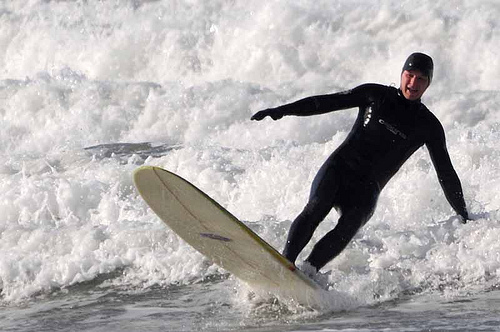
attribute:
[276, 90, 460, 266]
wet suit — tight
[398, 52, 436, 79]
cap — black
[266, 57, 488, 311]
suit — black, wet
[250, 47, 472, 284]
man — surfing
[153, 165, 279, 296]
line —  red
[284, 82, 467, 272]
wetsuit — black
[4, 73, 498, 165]
wave — white, crashing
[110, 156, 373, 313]
surfboard — large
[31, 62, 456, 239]
foam — white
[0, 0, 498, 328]
water — calm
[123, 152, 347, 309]
surfboard — white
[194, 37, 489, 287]
wetsuit — black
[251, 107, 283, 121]
glove — black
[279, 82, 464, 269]
bodysuit — black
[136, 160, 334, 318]
surfboard — large, white